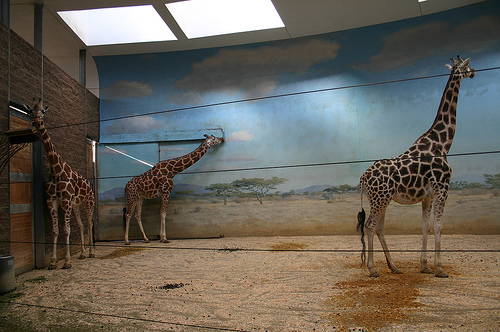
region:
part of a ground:
[262, 275, 300, 319]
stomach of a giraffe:
[385, 158, 427, 193]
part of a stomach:
[128, 159, 163, 198]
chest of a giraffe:
[33, 165, 68, 206]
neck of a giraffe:
[167, 138, 210, 183]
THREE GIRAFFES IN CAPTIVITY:
[19, 46, 485, 296]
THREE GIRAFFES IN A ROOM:
[33, 49, 491, 284]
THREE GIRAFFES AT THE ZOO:
[17, 53, 476, 303]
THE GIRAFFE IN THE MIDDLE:
[114, 111, 231, 258]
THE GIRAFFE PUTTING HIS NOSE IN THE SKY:
[107, 114, 229, 259]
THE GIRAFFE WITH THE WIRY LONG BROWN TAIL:
[347, 48, 478, 283]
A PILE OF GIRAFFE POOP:
[151, 272, 197, 302]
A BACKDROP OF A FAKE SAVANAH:
[89, 35, 492, 234]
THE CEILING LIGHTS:
[52, 1, 306, 53]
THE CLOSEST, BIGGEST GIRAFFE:
[329, 52, 488, 289]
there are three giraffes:
[19, 60, 499, 301]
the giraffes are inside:
[24, 35, 489, 238]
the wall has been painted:
[144, 106, 300, 204]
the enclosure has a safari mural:
[126, 80, 426, 259]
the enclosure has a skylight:
[139, 17, 333, 109]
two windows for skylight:
[116, 15, 341, 85]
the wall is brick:
[40, 68, 137, 139]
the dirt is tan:
[255, 277, 344, 327]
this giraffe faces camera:
[11, 80, 153, 210]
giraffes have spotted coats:
[22, 88, 300, 283]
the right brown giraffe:
[300, 35, 489, 284]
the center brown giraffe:
[98, 112, 260, 247]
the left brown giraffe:
[13, 90, 120, 282]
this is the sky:
[303, 73, 370, 122]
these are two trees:
[211, 168, 294, 214]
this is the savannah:
[236, 205, 271, 215]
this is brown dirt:
[205, 259, 322, 311]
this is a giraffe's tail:
[341, 175, 394, 282]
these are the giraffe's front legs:
[401, 146, 451, 285]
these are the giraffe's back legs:
[335, 167, 401, 282]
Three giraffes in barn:
[20, 35, 485, 330]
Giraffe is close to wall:
[103, 113, 236, 251]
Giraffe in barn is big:
[337, 38, 484, 295]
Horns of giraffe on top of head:
[446, 46, 463, 65]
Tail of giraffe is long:
[350, 166, 371, 269]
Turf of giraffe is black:
[352, 206, 373, 274]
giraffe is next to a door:
[20, 97, 103, 276]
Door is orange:
[1, 106, 46, 283]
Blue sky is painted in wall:
[95, 24, 497, 189]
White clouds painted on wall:
[183, 40, 340, 93]